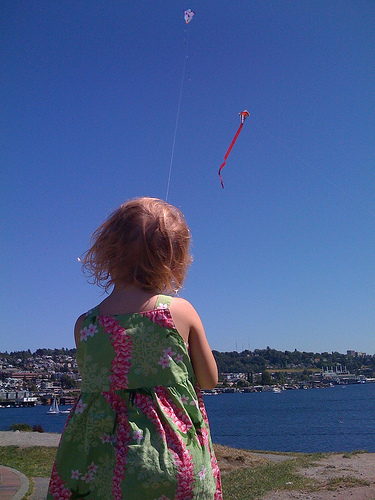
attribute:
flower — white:
[156, 353, 177, 374]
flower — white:
[161, 345, 178, 359]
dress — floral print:
[42, 289, 228, 496]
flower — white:
[172, 349, 186, 367]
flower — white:
[176, 390, 192, 409]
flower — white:
[80, 323, 97, 339]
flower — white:
[74, 323, 105, 342]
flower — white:
[81, 460, 100, 484]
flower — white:
[99, 432, 113, 444]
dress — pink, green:
[75, 310, 221, 498]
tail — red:
[224, 139, 236, 161]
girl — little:
[71, 195, 220, 487]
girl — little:
[58, 205, 231, 491]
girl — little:
[71, 199, 208, 490]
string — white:
[163, 166, 173, 183]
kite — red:
[238, 108, 250, 125]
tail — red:
[223, 144, 235, 158]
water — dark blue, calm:
[4, 385, 372, 452]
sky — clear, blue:
[3, 2, 373, 351]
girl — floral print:
[47, 189, 228, 497]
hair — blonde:
[79, 194, 199, 294]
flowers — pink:
[100, 308, 130, 486]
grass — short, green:
[224, 460, 291, 495]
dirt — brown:
[299, 449, 371, 495]